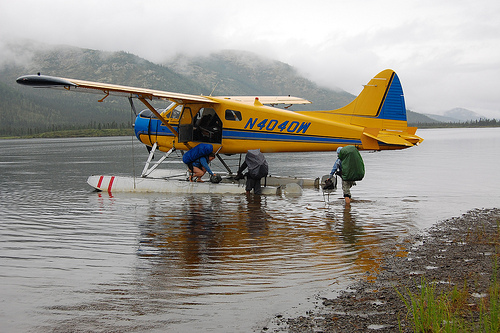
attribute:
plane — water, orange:
[15, 68, 425, 196]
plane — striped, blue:
[39, 60, 419, 187]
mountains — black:
[6, 40, 483, 172]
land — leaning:
[256, 207, 498, 332]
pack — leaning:
[339, 147, 363, 179]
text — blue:
[242, 118, 314, 137]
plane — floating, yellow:
[11, 45, 428, 206]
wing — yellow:
[207, 89, 315, 116]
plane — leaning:
[13, 60, 440, 245]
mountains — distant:
[0, 32, 499, 137]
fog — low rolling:
[1, 0, 487, 128]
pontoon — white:
[86, 172, 281, 198]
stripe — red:
[108, 172, 115, 200]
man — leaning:
[235, 147, 269, 194]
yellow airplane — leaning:
[11, 57, 426, 212]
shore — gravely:
[280, 205, 499, 326]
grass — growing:
[399, 284, 493, 331]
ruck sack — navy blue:
[244, 142, 270, 182]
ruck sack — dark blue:
[180, 139, 213, 165]